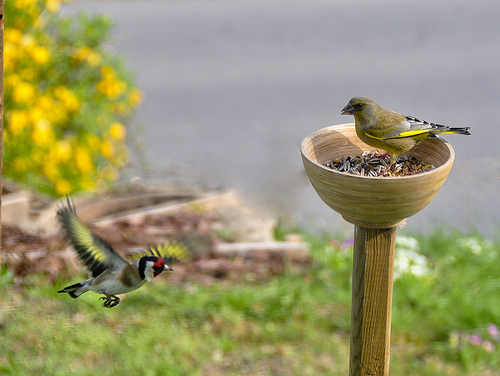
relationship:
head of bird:
[335, 87, 372, 127] [335, 86, 473, 156]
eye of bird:
[352, 100, 368, 116] [335, 89, 499, 163]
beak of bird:
[153, 255, 180, 272] [359, 111, 430, 139]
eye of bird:
[352, 100, 364, 111] [340, 94, 471, 177]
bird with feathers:
[334, 91, 455, 175] [366, 105, 395, 139]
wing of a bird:
[362, 124, 432, 144] [335, 82, 480, 164]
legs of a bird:
[366, 150, 406, 172] [339, 96, 471, 155]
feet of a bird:
[375, 150, 392, 173] [340, 95, 468, 170]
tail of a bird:
[431, 121, 473, 137] [335, 99, 447, 161]